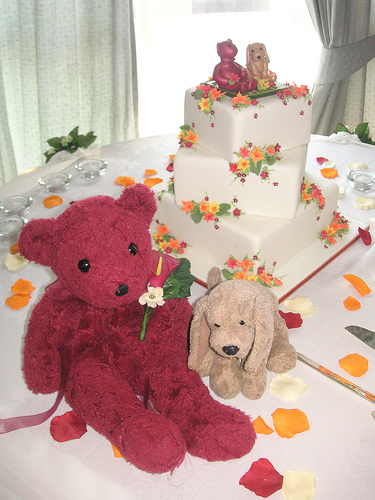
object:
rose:
[278, 309, 303, 329]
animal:
[187, 280, 297, 400]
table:
[0, 130, 374, 497]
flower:
[138, 285, 165, 307]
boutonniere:
[138, 254, 196, 342]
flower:
[228, 141, 283, 186]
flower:
[177, 122, 196, 147]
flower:
[180, 195, 245, 230]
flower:
[299, 176, 326, 221]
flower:
[151, 218, 192, 259]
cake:
[149, 38, 340, 271]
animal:
[18, 183, 256, 475]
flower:
[238, 457, 283, 500]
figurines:
[213, 39, 257, 92]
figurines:
[245, 42, 276, 88]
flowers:
[279, 80, 314, 116]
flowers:
[190, 76, 229, 129]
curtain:
[306, 0, 375, 136]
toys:
[188, 277, 298, 400]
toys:
[17, 183, 255, 475]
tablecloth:
[2, 127, 374, 499]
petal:
[343, 274, 372, 296]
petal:
[343, 295, 362, 311]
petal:
[338, 353, 369, 377]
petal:
[277, 310, 302, 330]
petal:
[283, 293, 317, 318]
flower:
[222, 250, 284, 292]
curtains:
[0, 0, 142, 184]